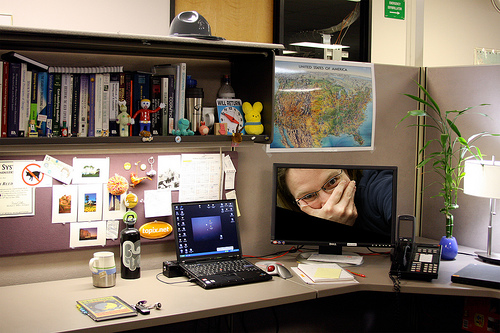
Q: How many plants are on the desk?
A: One.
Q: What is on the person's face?
A: Glasses.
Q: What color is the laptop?
A: Black.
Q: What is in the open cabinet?
A: Books.